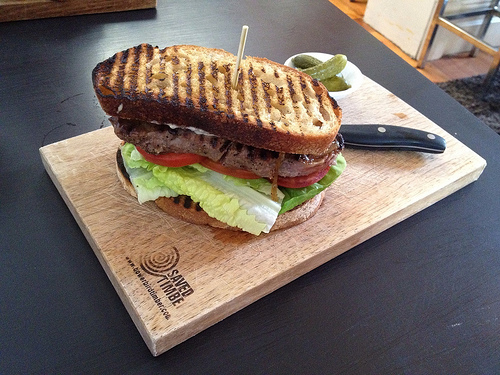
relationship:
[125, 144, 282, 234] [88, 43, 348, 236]
lettuce on sandwich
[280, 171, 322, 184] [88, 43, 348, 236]
tomato on sandwich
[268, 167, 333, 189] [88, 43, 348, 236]
tomato on sandwich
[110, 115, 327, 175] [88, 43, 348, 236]
steak on sandwich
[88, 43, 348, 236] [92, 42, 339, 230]
sandwich on board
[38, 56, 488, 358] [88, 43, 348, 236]
board holding sandwich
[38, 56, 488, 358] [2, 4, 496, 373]
board on table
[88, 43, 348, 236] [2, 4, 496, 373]
sandwich on table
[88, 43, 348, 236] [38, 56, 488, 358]
sandwich on board